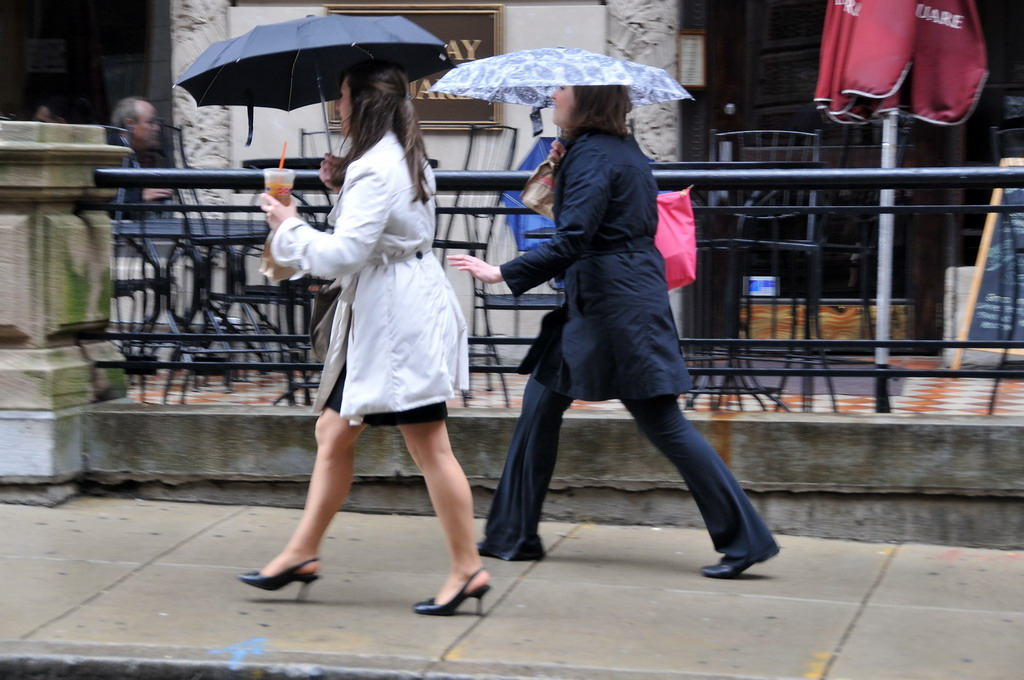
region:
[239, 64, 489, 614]
A young woman carrying blue umbrella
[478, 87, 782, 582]
A young woman in blue pant suit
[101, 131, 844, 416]
Outdoor dining tables and chairs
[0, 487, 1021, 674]
The sidewalk the two women are walking on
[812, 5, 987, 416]
Folded red parasol with its stand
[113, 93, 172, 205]
A man in an outdoor eatery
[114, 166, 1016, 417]
A metalliv railing on the edge of the sidewalk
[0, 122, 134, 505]
A cement pillar supporting the railing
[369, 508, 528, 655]
shoe on the girl's foot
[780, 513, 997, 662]
line on the ground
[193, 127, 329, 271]
drink in girl's hand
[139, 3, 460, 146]
umbrella over girl's head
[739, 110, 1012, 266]
post next to the girls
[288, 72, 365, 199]
handle of the object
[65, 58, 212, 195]
man in the distance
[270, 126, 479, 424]
A female white jacket.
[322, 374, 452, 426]
A very short black skirt.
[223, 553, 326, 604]
A black high heel.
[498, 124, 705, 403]
A very dark colored jacket.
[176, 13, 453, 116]
A dark black umbrella.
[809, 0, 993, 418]
A red and white umbrella.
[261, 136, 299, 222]
A drink with an orange straw.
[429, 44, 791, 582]
A woman dressed in professional attire.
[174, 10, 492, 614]
girl walking on the sidewalk with a black umbrella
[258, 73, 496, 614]
girl in a white coat carrying an iced coffee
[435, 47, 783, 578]
girl in a black coat with a blue umbrella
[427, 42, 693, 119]
floral design on the canopy of the umbrella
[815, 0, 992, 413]
red sun umbrella at the sidewalk cafe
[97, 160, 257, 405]
metal safety rail on the side of the walkway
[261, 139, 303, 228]
red straw in the plastic iced coffee cup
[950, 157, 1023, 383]
sidewalk chalkboard restaurant menu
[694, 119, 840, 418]
metal chair and table of the outdoor cafe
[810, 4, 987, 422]
the red umbrella is closed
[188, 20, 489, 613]
woman carrying an umbrella over her head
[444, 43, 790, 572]
woman carrying an umbrella over her head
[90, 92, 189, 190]
man is sitting inside the building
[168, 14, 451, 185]
umbrella is dark blue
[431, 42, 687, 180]
umbrella is blue and white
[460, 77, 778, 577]
woman is wearing pants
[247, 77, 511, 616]
woman is wearing a skirt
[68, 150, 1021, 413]
tables and chairs are all empty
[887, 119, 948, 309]
glass window on the building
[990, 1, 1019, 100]
glass window on the building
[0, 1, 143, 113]
glass window on the building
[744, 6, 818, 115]
glass window on the building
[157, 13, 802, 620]
two women are walking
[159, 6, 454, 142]
woman holding a blue umbrella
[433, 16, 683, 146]
woman holding a floral umbrella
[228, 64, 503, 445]
a white trench coat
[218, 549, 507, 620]
black pair of pumps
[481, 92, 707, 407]
a blue trench coat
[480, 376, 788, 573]
pair of blue pants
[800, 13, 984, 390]
umbrella on the side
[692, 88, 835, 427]
chair on a patio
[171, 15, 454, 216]
a black umbrella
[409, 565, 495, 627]
a woman's black sandal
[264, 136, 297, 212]
a plastic cup with a straw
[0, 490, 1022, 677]
a paved sidewalk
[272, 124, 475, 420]
a woman's white coat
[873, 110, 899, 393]
a long gray pole